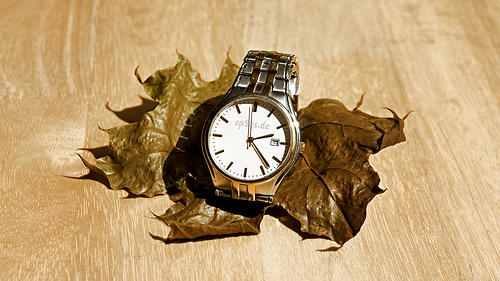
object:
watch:
[207, 56, 307, 223]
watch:
[197, 47, 306, 205]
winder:
[298, 138, 306, 153]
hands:
[246, 138, 271, 169]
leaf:
[303, 95, 412, 162]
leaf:
[91, 55, 240, 192]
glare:
[283, 116, 303, 132]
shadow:
[156, 222, 253, 248]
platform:
[5, 5, 96, 87]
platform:
[384, 3, 499, 279]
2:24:
[210, 104, 287, 179]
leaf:
[305, 192, 360, 241]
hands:
[250, 137, 267, 170]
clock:
[202, 95, 297, 184]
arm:
[244, 107, 252, 137]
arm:
[252, 134, 277, 141]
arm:
[250, 143, 270, 170]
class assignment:
[2, 4, 499, 276]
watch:
[203, 93, 307, 202]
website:
[232, 117, 270, 130]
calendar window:
[267, 138, 280, 145]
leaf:
[317, 142, 355, 179]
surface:
[2, 130, 94, 266]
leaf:
[102, 133, 144, 189]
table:
[196, 3, 286, 46]